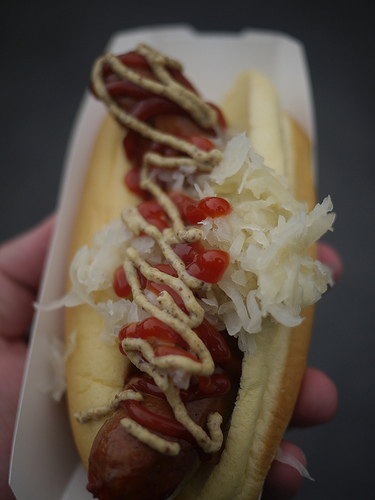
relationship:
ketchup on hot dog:
[102, 47, 232, 455] [84, 47, 242, 497]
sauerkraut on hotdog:
[46, 141, 333, 331] [84, 54, 238, 498]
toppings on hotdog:
[32, 42, 335, 460] [63, 46, 315, 499]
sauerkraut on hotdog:
[32, 129, 336, 351] [84, 54, 238, 498]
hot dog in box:
[60, 46, 320, 365] [6, 26, 321, 498]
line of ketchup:
[124, 145, 224, 431] [129, 167, 232, 227]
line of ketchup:
[124, 145, 224, 431] [110, 238, 230, 291]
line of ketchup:
[124, 145, 224, 431] [117, 317, 235, 395]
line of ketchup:
[124, 145, 224, 431] [121, 376, 215, 460]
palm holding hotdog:
[2, 211, 50, 498] [35, 42, 336, 496]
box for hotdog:
[79, 95, 344, 423] [106, 185, 219, 472]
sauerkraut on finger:
[278, 439, 312, 486] [268, 432, 319, 485]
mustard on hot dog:
[99, 59, 217, 455] [63, 34, 322, 494]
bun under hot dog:
[221, 75, 316, 477] [84, 47, 242, 497]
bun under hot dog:
[53, 120, 130, 451] [84, 47, 242, 497]